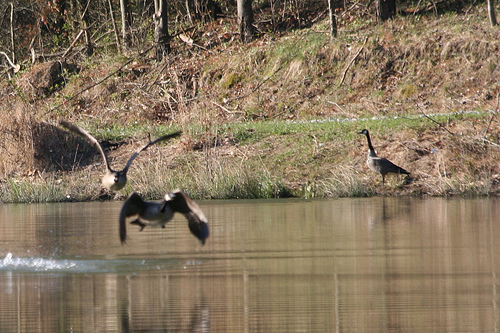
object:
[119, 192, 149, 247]
bird wings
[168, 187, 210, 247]
bird wings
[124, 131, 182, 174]
bird wings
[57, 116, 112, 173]
bird wings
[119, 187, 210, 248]
bird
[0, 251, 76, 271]
splash mark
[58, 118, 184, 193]
bird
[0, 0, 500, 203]
embankment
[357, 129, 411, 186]
bird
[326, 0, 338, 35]
trunk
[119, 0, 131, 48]
trunk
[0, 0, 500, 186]
hill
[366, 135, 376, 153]
neck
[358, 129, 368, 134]
face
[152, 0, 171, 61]
tree trunk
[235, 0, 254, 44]
tree trunk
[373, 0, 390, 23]
tree trunk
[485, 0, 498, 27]
tree trunk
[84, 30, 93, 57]
tree trunk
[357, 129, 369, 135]
head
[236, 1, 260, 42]
trunk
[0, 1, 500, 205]
grass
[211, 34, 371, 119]
tree limbs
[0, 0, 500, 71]
trees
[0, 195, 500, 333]
embarkments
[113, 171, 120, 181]
head